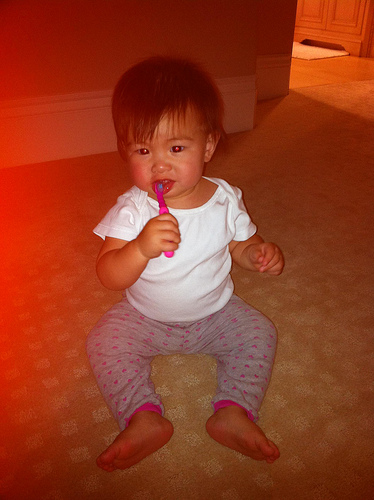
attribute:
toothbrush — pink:
[152, 178, 180, 258]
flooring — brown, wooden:
[274, 58, 373, 109]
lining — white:
[211, 390, 239, 408]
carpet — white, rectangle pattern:
[0, 80, 372, 498]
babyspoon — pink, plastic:
[154, 184, 175, 256]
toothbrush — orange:
[151, 182, 168, 212]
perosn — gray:
[70, 56, 287, 407]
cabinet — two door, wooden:
[288, 1, 372, 55]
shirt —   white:
[91, 176, 256, 323]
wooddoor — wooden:
[294, 0, 367, 42]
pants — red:
[82, 300, 286, 423]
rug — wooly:
[301, 36, 356, 62]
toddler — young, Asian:
[48, 50, 298, 497]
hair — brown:
[109, 53, 223, 200]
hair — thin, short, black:
[108, 55, 225, 153]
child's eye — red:
[165, 140, 192, 159]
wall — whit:
[2, 0, 289, 135]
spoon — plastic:
[145, 178, 178, 262]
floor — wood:
[294, 58, 341, 79]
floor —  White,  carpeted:
[261, 78, 372, 498]